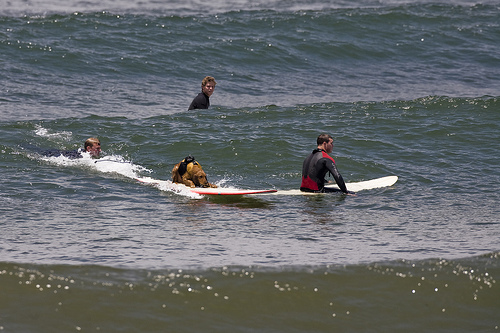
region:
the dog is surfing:
[133, 134, 283, 256]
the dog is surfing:
[144, 132, 230, 239]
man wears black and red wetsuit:
[287, 127, 429, 227]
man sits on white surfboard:
[274, 132, 416, 209]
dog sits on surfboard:
[147, 142, 281, 225]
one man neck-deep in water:
[53, 95, 132, 195]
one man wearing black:
[166, 62, 243, 130]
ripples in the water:
[12, 7, 494, 306]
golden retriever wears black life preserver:
[151, 140, 276, 216]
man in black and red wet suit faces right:
[282, 120, 408, 224]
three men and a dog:
[41, 47, 415, 235]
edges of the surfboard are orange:
[168, 153, 293, 235]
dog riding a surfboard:
[155, 143, 265, 221]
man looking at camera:
[130, 60, 240, 121]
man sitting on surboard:
[290, 130, 425, 245]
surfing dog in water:
[138, 150, 249, 220]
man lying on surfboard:
[27, 126, 136, 184]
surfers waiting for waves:
[45, 89, 455, 273]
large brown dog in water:
[157, 151, 220, 201]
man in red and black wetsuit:
[265, 113, 360, 199]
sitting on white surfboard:
[305, 168, 424, 202]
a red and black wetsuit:
[295, 145, 345, 195]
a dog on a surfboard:
[170, 155, 210, 185]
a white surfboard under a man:
[275, 125, 391, 200]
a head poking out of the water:
[80, 130, 100, 155]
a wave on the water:
[0, 75, 496, 165]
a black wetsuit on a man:
[185, 70, 220, 106]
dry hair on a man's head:
[196, 72, 216, 87]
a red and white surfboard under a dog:
[183, 178, 276, 201]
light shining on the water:
[119, 217, 400, 265]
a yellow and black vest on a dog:
[175, 155, 201, 172]